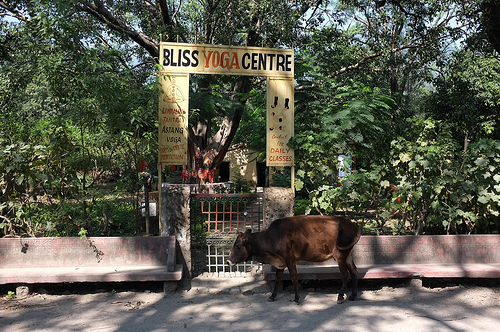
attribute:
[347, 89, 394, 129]
leaves — green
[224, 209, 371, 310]
cow — brown, small, dark brown, colored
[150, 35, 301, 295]
center — yellow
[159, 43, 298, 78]
bliss yoga center — black, red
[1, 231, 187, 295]
benche — red, brick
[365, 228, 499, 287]
bench — red, colored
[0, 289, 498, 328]
ground — cement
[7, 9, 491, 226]
trees — outdoor photo, colored, green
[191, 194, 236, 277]
fence — metal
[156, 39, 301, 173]
sign — yellow, tan, black, red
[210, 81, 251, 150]
trunk — tree trunk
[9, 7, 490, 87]
sky — clear, blue, colored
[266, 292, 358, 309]
hooves — black